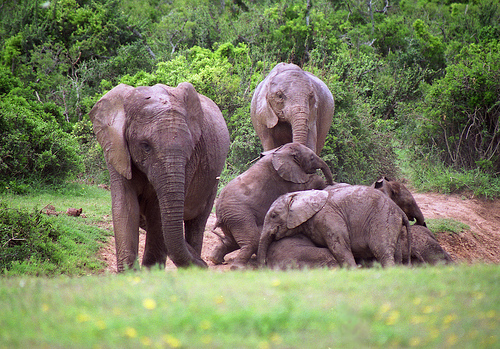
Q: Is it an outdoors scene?
A: Yes, it is outdoors.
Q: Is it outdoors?
A: Yes, it is outdoors.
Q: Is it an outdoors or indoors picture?
A: It is outdoors.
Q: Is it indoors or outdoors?
A: It is outdoors.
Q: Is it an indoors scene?
A: No, it is outdoors.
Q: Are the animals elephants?
A: Yes, all the animals are elephants.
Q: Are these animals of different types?
A: No, all the animals are elephants.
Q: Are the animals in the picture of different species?
A: No, all the animals are elephants.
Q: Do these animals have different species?
A: No, all the animals are elephants.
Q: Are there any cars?
A: No, there are no cars.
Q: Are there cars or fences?
A: No, there are no cars or fences.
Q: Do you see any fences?
A: No, there are no fences.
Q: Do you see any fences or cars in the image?
A: No, there are no fences or cars.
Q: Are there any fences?
A: No, there are no fences.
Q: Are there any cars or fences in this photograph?
A: No, there are no fences or cars.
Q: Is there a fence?
A: No, there are no fences.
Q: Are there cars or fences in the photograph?
A: No, there are no fences or cars.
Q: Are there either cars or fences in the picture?
A: No, there are no fences or cars.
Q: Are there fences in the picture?
A: No, there are no fences.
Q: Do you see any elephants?
A: Yes, there are elephants.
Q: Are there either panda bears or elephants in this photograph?
A: Yes, there are elephants.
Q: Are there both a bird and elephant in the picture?
A: No, there are elephants but no birds.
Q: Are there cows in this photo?
A: No, there are no cows.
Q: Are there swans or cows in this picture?
A: No, there are no cows or swans.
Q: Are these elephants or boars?
A: These are elephants.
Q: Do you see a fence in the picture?
A: No, there are no fences.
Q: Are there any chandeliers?
A: No, there are no chandeliers.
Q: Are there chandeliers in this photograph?
A: No, there are no chandeliers.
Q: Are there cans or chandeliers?
A: No, there are no chandeliers or cans.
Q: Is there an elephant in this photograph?
A: Yes, there is an elephant.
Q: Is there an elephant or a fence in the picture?
A: Yes, there is an elephant.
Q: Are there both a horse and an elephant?
A: No, there is an elephant but no horses.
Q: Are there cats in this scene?
A: No, there are no cats.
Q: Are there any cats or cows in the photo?
A: No, there are no cats or cows.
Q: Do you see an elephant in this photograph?
A: Yes, there are elephants.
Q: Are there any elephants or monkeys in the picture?
A: Yes, there are elephants.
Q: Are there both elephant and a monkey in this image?
A: No, there are elephants but no monkeys.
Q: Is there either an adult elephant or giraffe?
A: Yes, there are adult elephants.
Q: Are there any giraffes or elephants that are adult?
A: Yes, the elephants are adult.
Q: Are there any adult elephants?
A: Yes, there are adult elephants.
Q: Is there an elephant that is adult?
A: Yes, there are elephants that are adult.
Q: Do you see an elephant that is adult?
A: Yes, there are elephants that are adult.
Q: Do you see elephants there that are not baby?
A: Yes, there are adult elephants.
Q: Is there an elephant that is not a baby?
A: Yes, there are adult elephants.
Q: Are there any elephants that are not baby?
A: Yes, there are adult elephants.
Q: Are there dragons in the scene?
A: No, there are no dragons.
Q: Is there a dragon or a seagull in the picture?
A: No, there are no dragons or seagulls.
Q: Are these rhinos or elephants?
A: These are elephants.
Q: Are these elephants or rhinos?
A: These are elephants.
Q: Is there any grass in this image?
A: Yes, there is grass.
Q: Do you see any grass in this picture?
A: Yes, there is grass.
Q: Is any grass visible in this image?
A: Yes, there is grass.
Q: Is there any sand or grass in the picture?
A: Yes, there is grass.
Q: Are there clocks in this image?
A: No, there are no clocks.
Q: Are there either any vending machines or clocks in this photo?
A: No, there are no clocks or vending machines.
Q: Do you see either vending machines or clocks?
A: No, there are no clocks or vending machines.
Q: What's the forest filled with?
A: The forest is filled with tree.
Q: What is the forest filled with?
A: The forest is filled with tree.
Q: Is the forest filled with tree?
A: Yes, the forest is filled with tree.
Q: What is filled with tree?
A: The forest is filled with tree.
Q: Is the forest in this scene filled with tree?
A: Yes, the forest is filled with tree.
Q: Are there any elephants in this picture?
A: Yes, there are elephants.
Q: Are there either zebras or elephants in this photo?
A: Yes, there are elephants.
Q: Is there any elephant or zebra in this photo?
A: Yes, there are elephants.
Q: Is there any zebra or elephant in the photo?
A: Yes, there are elephants.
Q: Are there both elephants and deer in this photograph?
A: No, there are elephants but no deer.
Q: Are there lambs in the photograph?
A: No, there are no lambs.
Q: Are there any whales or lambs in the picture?
A: No, there are no lambs or whales.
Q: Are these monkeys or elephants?
A: These are elephants.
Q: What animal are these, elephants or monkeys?
A: These are elephants.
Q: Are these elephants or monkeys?
A: These are elephants.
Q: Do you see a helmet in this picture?
A: No, there are no helmets.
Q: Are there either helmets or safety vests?
A: No, there are no helmets or safety vests.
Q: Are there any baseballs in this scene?
A: No, there are no baseballs.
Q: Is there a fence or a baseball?
A: No, there are no baseballs or fences.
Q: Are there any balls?
A: No, there are no balls.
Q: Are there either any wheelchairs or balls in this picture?
A: No, there are no balls or wheelchairs.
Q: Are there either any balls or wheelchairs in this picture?
A: No, there are no balls or wheelchairs.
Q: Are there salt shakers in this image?
A: No, there are no salt shakers.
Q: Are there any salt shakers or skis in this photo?
A: No, there are no salt shakers or skis.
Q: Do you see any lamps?
A: No, there are no lamps.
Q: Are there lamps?
A: No, there are no lamps.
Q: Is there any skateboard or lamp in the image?
A: No, there are no lamps or skateboards.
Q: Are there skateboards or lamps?
A: No, there are no lamps or skateboards.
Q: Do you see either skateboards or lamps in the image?
A: No, there are no lamps or skateboards.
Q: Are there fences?
A: No, there are no fences.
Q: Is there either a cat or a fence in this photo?
A: No, there are no fences or cats.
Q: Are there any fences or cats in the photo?
A: No, there are no fences or cats.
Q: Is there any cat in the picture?
A: No, there are no cats.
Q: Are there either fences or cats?
A: No, there are no cats or fences.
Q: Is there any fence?
A: No, there are no fences.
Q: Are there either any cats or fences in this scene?
A: No, there are no fences or cats.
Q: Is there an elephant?
A: Yes, there is an elephant.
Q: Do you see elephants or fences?
A: Yes, there is an elephant.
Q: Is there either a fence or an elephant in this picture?
A: Yes, there is an elephant.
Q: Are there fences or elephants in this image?
A: Yes, there is an elephant.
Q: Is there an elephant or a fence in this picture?
A: Yes, there is an elephant.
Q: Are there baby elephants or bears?
A: Yes, there is a baby elephant.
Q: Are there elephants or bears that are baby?
A: Yes, the elephant is a baby.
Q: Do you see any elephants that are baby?
A: Yes, there is a baby elephant.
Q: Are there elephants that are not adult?
A: Yes, there is an baby elephant.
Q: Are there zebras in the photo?
A: No, there are no zebras.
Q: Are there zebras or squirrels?
A: No, there are no zebras or squirrels.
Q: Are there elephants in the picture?
A: Yes, there is an elephant.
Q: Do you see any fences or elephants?
A: Yes, there is an elephant.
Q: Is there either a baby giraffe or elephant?
A: Yes, there is a baby elephant.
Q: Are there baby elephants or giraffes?
A: Yes, there is a baby elephant.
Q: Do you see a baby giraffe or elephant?
A: Yes, there is a baby elephant.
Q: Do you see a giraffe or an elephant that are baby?
A: Yes, the elephant is a baby.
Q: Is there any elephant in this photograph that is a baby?
A: Yes, there is a baby elephant.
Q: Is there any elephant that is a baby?
A: Yes, there is an elephant that is a baby.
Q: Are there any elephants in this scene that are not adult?
A: Yes, there is an baby elephant.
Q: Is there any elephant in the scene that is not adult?
A: Yes, there is an baby elephant.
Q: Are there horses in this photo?
A: No, there are no horses.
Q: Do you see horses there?
A: No, there are no horses.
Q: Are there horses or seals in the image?
A: No, there are no horses or seals.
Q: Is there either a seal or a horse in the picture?
A: No, there are no horses or seals.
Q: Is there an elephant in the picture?
A: Yes, there is an elephant.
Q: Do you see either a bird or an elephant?
A: Yes, there is an elephant.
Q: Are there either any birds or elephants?
A: Yes, there is an elephant.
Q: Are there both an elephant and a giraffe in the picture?
A: No, there is an elephant but no giraffes.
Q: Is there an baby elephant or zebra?
A: Yes, there is a baby elephant.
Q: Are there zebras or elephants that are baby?
A: Yes, the elephant is a baby.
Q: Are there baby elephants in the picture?
A: Yes, there is a baby elephant.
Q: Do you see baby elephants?
A: Yes, there is a baby elephant.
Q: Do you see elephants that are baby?
A: Yes, there is an elephant that is a baby.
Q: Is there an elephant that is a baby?
A: Yes, there is an elephant that is a baby.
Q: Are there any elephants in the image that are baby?
A: Yes, there is an elephant that is a baby.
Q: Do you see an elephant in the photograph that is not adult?
A: Yes, there is an baby elephant.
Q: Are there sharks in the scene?
A: No, there are no sharks.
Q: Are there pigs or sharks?
A: No, there are no sharks or pigs.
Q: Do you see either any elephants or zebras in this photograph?
A: Yes, there is an elephant.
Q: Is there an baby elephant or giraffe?
A: Yes, there is a baby elephant.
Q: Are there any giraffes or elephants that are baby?
A: Yes, the elephant is a baby.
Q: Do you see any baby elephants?
A: Yes, there is a baby elephant.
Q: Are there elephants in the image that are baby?
A: Yes, there is an elephant that is a baby.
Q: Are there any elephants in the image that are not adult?
A: Yes, there is an baby elephant.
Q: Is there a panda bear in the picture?
A: No, there are no pandas.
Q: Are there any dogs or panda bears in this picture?
A: No, there are no panda bears or dogs.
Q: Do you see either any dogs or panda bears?
A: No, there are no panda bears or dogs.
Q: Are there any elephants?
A: Yes, there are elephants.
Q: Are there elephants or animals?
A: Yes, there are elephants.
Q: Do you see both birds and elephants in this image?
A: No, there are elephants but no birds.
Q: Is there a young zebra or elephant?
A: Yes, there are young elephants.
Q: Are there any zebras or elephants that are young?
A: Yes, the elephants are young.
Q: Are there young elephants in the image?
A: Yes, there are young elephants.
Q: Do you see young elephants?
A: Yes, there are young elephants.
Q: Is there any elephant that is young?
A: Yes, there are elephants that are young.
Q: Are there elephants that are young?
A: Yes, there are elephants that are young.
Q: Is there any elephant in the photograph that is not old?
A: Yes, there are young elephants.